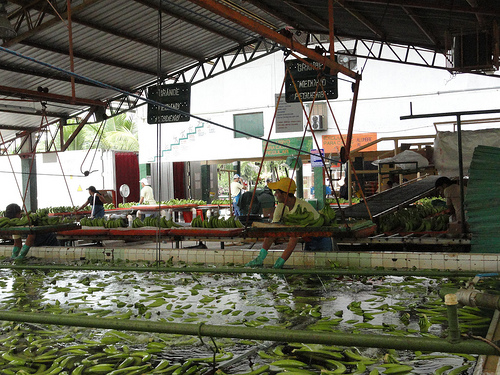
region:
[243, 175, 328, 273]
worker at a produce stand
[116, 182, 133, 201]
scale near a table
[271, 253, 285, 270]
green glove on a left hand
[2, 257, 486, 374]
tub of bananas and water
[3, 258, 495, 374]
a large vat of water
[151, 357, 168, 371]
a bright green banana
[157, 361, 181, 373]
a bright green banana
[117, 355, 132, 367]
a bright green banana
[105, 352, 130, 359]
a bright green banana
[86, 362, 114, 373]
a bright green banana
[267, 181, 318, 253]
THIS IS A PERSON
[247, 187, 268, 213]
THIS IS A PERSON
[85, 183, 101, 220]
THIS IS A PERSON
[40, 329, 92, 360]
THESE ARE RAW BANANAS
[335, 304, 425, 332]
THESE ARE RAW BANANAS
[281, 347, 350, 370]
THESE ARE RAW BANANAS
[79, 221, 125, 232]
THESE ARE RAW BANANAS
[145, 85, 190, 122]
A black sign hanging from a ceiling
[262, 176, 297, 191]
A yellow cap on a man's head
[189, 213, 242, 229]
Green bananas on a table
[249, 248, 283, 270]
Green gloves on a man's hand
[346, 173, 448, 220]
A conveyor belt for vegetables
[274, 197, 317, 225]
A white shirt on a person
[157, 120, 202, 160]
A zig zag line on a wall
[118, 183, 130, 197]
A round scale near vegetables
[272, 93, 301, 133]
A white sign on a wall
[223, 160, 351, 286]
this is a man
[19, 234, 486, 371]
bananas in the water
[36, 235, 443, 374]
the bananas are green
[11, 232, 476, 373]
the water is dark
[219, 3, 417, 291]
bananas on a scale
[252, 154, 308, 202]
man wearing a yellow hat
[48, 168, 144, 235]
person in the background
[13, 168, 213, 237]
bananas on side tables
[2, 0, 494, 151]
the roof is grey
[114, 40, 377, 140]
signs suspended from roof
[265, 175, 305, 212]
The person has a hat on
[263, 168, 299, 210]
The person has a yellow hat on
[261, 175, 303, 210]
The person has a cap on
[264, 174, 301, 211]
The person has a yellow cap on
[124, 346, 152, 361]
green fish in the water tank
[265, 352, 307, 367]
green fish in the water tank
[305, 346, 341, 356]
green fish in the water tank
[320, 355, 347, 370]
green fish in the water tank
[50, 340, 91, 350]
green fish in the water tank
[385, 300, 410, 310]
green fish in the water tank